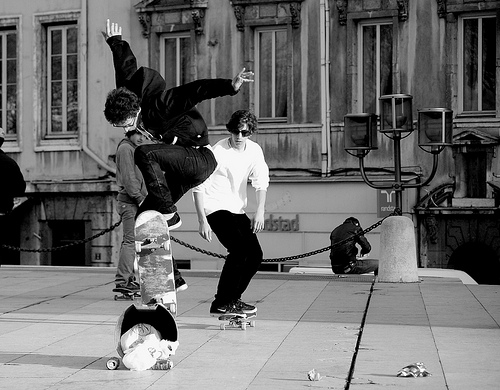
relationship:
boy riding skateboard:
[189, 108, 272, 320] [202, 302, 259, 327]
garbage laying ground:
[291, 347, 433, 387] [0, 263, 499, 388]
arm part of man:
[101, 17, 139, 87] [89, 29, 224, 224]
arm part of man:
[163, 67, 254, 106] [89, 29, 224, 224]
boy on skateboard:
[99, 17, 257, 302] [130, 203, 180, 363]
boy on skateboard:
[189, 108, 272, 320] [203, 292, 292, 352]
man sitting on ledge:
[322, 215, 378, 279] [289, 263, 479, 286]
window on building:
[243, 22, 295, 124] [3, 7, 483, 277]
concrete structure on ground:
[346, 207, 441, 299] [263, 285, 438, 343]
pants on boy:
[205, 209, 262, 302] [189, 108, 272, 320]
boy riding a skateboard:
[189, 108, 272, 320] [214, 307, 261, 337]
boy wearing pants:
[189, 108, 272, 320] [197, 202, 259, 317]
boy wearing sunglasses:
[189, 108, 272, 320] [226, 125, 256, 138]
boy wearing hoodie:
[99, 17, 257, 302] [100, 38, 232, 213]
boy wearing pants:
[189, 108, 272, 320] [209, 207, 261, 349]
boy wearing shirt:
[189, 108, 272, 320] [189, 139, 276, 218]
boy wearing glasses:
[193, 110, 265, 314] [230, 127, 250, 137]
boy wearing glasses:
[99, 17, 257, 302] [105, 116, 136, 127]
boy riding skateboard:
[189, 108, 272, 320] [219, 306, 248, 327]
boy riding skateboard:
[99, 82, 180, 134] [132, 211, 177, 317]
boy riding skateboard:
[114, 129, 149, 153] [109, 270, 135, 301]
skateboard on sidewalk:
[219, 306, 248, 327] [194, 324, 337, 375]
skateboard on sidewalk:
[132, 211, 177, 317] [194, 324, 337, 375]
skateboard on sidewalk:
[109, 270, 135, 301] [194, 324, 337, 375]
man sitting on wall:
[326, 215, 380, 275] [293, 259, 481, 284]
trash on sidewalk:
[290, 346, 447, 383] [1, 264, 499, 389]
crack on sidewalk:
[345, 280, 374, 387] [1, 264, 499, 389]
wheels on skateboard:
[134, 240, 169, 253] [130, 211, 181, 326]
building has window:
[3, 7, 483, 277] [256, 27, 288, 123]